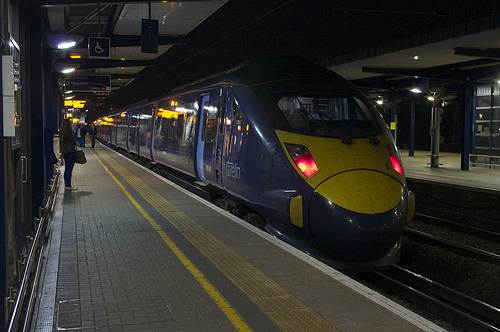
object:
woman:
[60, 115, 90, 191]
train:
[91, 64, 414, 263]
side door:
[193, 97, 215, 190]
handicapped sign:
[85, 37, 111, 61]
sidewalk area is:
[77, 140, 181, 206]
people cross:
[80, 117, 104, 149]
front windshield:
[279, 95, 377, 140]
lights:
[54, 60, 80, 74]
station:
[6, 4, 500, 331]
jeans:
[61, 155, 79, 188]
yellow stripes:
[99, 156, 161, 220]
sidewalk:
[79, 134, 222, 220]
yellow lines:
[101, 157, 246, 282]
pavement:
[86, 208, 163, 290]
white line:
[110, 147, 236, 218]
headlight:
[290, 145, 324, 179]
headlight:
[382, 150, 404, 179]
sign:
[135, 16, 163, 59]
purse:
[75, 148, 89, 165]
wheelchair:
[93, 43, 103, 57]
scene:
[1, 8, 499, 332]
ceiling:
[45, 3, 222, 106]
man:
[183, 118, 199, 145]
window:
[182, 107, 199, 147]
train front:
[237, 69, 424, 249]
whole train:
[91, 68, 416, 266]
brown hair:
[57, 114, 76, 128]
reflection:
[116, 114, 183, 165]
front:
[277, 129, 413, 213]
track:
[360, 259, 499, 331]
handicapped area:
[65, 26, 120, 195]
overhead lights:
[47, 31, 85, 53]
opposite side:
[402, 35, 500, 250]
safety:
[109, 158, 217, 237]